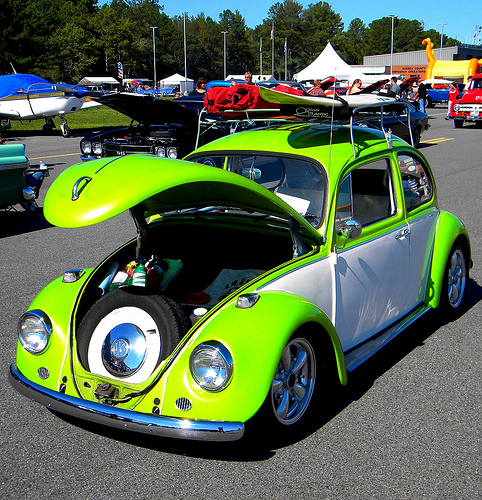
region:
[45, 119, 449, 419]
a green and white vehicle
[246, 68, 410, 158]
a surf board on top of a car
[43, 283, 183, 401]
a spare wheel for a car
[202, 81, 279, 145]
two red bags on top of a car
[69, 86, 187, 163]
a black car with the hood up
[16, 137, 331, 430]
a green and white car with the hood up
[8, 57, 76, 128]
a plane covered with a blue tarp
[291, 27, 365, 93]
a white tent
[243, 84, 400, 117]
a white surf board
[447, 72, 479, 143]
a red truck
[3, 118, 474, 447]
a green and white Volkswagen beetle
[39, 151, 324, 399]
open front hood on beetle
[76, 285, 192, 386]
spare tire in trunk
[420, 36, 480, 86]
yellow and orange bouncy house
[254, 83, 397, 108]
surfboard on top of car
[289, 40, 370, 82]
triangular top of white tent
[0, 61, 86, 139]
blue tarp covered boat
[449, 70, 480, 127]
front end of red vehicle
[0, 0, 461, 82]
trees on edge of field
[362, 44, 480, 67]
building behind bouncy house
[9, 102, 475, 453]
bright green Volkswagen Beetle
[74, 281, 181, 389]
spare tire in front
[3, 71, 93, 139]
airplane covered with blue tarp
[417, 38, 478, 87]
orange and yellow bounce house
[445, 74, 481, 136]
vintage red truck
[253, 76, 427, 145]
surfboard on a roof rack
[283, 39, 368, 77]
white tent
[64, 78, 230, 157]
car with open hood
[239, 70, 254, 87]
man wearing sunglasses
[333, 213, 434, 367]
car has a white door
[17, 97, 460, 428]
lime green and white vw beetle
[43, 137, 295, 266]
raised hood of car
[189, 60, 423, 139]
rack on top of vw beetle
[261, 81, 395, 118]
white surfboard attached to rack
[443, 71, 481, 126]
red truck in parking lot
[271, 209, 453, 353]
white side panel of vw beetle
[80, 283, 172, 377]
spare tire inside of front trunk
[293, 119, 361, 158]
shadow of surfboard on car roof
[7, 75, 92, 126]
white boat in parking lot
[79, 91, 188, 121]
raised hood of black car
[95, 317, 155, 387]
VW Car hub cap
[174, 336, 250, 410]
Left front hub cap on car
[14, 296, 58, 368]
Right front hub cap on car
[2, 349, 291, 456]
Chrome bumper on VW Car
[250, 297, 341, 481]
Left front VW tire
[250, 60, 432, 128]
Surf board on car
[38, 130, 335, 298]
Front hood open on VW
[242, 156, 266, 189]
Rear view mirror on a car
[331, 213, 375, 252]
Left side mirror on car